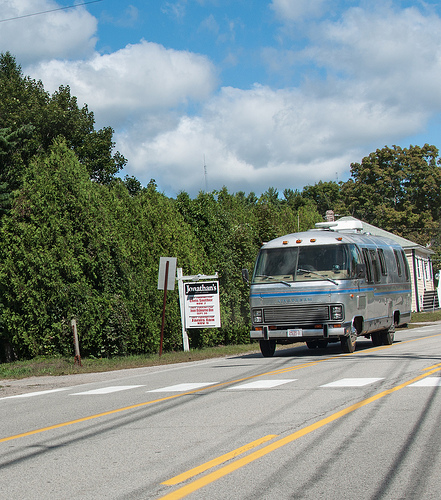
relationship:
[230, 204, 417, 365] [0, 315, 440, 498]
van traveling on road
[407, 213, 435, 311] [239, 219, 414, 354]
building behind motor home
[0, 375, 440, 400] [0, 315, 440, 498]
crosswalk in road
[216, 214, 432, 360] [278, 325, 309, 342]
motor home has license plate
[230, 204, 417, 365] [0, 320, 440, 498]
van on street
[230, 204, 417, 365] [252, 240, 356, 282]
van has windshield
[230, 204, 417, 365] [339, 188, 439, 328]
van obstructs house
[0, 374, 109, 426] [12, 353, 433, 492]
driveway comes off road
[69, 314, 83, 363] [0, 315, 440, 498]
pole on side of a road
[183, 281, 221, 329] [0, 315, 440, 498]
sign by side of road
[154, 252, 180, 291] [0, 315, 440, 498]
sign by side of road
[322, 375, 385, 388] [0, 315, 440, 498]
box on road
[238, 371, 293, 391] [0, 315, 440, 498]
box on road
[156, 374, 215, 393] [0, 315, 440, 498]
box on road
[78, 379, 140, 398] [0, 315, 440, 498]
box on road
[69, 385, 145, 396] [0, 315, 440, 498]
box on road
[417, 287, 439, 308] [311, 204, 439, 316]
stairs in front of house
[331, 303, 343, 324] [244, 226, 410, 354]
headlights on camper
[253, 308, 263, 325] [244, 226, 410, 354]
headlights on camper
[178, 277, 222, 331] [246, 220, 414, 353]
sign next to motorhome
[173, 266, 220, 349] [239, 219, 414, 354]
white post next to motor home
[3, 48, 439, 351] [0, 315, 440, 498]
foliage by road